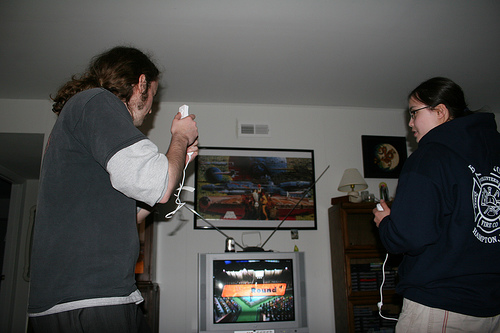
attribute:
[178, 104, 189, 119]
controller — white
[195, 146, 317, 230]
picture — framed, hanging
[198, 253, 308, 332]
tv — silver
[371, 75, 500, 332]
woman — playing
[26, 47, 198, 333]
man — playing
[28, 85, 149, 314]
shirt — grey